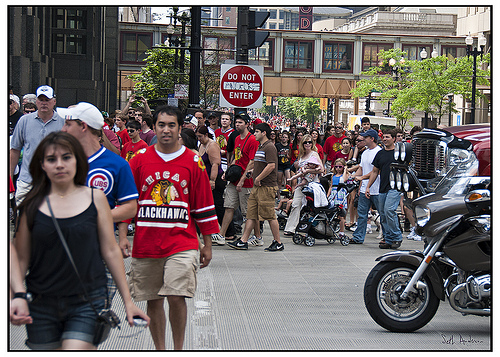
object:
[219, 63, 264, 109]
sign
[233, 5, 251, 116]
pole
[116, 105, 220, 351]
man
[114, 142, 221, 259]
shirt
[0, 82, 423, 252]
crowd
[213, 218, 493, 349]
street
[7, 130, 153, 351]
woman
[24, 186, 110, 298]
tanktop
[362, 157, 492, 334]
bike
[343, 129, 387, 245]
man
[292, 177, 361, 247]
stroller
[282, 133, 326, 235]
woman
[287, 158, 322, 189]
baby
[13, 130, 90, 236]
hair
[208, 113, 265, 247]
man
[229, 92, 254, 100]
words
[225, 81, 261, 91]
graffiti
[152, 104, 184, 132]
hair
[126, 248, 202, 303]
shorts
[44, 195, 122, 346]
purse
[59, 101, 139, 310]
man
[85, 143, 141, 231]
jersey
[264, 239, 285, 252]
shoes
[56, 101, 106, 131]
hat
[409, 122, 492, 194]
truck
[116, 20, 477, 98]
skyway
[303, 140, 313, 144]
glasses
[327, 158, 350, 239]
girl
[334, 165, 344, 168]
glasses